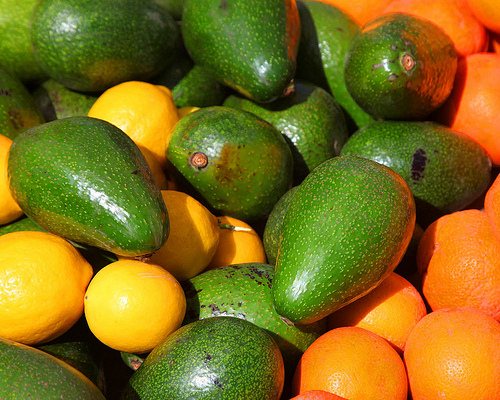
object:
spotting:
[448, 329, 453, 337]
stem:
[401, 53, 416, 69]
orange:
[293, 327, 408, 400]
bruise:
[210, 144, 245, 189]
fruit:
[82, 259, 186, 352]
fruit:
[84, 81, 179, 164]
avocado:
[272, 156, 417, 325]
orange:
[437, 52, 500, 165]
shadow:
[292, 0, 335, 98]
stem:
[217, 219, 252, 232]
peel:
[119, 316, 285, 400]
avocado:
[340, 122, 494, 215]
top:
[290, 390, 348, 399]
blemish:
[410, 148, 428, 185]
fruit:
[341, 120, 494, 213]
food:
[0, 231, 91, 346]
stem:
[191, 152, 207, 167]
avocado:
[163, 106, 294, 217]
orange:
[329, 271, 429, 354]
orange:
[402, 308, 499, 400]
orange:
[417, 209, 500, 316]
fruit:
[344, 13, 459, 119]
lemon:
[118, 190, 221, 280]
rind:
[83, 260, 187, 354]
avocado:
[181, 1, 301, 103]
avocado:
[297, 0, 378, 129]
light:
[62, 169, 139, 237]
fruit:
[7, 116, 170, 258]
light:
[285, 248, 327, 303]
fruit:
[269, 151, 419, 329]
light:
[197, 131, 226, 157]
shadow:
[301, 196, 438, 335]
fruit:
[181, 263, 326, 367]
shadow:
[175, 276, 202, 327]